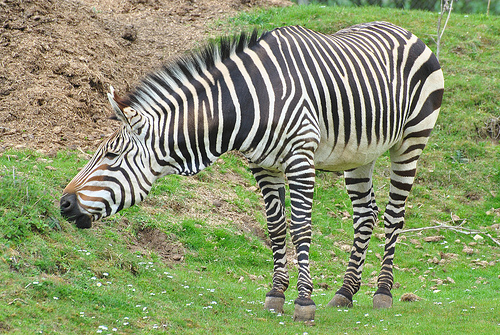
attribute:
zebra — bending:
[64, 24, 433, 299]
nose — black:
[52, 195, 94, 239]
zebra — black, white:
[61, 21, 445, 319]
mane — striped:
[111, 27, 275, 122]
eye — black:
[91, 148, 136, 173]